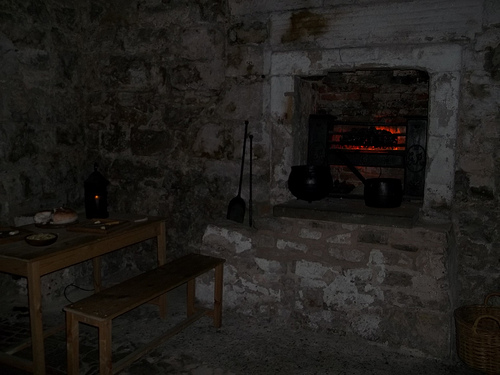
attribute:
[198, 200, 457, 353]
hearth — stone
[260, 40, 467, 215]
mantle — stone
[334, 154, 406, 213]
pot — black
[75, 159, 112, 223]
lantern — black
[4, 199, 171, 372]
table — wooden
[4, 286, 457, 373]
floor — block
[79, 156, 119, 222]
lantern — metal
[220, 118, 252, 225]
shovel — metal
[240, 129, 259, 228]
poker — fireplace, metal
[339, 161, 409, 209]
pot — metal, cooking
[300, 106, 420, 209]
stove — metal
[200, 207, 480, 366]
wall — brick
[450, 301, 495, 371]
basket — wicker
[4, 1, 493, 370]
room — dark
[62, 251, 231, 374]
long bench — brown, wood, wooden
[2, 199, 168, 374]
long table — wood, brown, wooden, dinner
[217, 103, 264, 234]
black untensil — fire, fireplace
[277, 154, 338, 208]
cast iron pot — cast iron, black